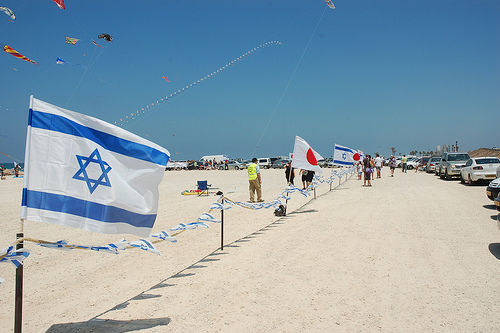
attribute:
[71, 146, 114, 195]
star — blue, white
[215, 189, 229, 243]
post — black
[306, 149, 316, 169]
circle — red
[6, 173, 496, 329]
sand — clean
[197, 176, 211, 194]
chair — blue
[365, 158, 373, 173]
shoulder bag — grey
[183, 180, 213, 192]
beach chair — small, blue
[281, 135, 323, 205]
flag — white, red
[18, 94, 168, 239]
flag — large, blue, white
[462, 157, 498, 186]
car — white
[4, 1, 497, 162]
sky — clear, blue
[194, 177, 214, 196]
chair — on the sand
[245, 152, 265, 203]
man — standing by a flag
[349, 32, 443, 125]
sky — above the kites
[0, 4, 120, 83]
kites — above the beach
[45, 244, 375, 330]
sand — at the beach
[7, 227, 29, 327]
pole —  Israeli flag 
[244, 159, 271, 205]
man —  yellow shirt 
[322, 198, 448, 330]
beach —  sandy 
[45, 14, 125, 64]
kite — sky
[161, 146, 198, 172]
car — parked white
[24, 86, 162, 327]
pole — flag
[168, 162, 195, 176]
suv — silver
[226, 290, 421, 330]
sand —  flag shadow 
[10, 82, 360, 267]
beach — international flags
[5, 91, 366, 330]
beach — various country flags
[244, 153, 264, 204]
man —  neon vest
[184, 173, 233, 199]
chair — blue beach 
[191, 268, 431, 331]
beach —  israeli flags , japanese  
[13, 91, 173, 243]
flag — blue, white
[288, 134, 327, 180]
flag — white, red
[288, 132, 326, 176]
flag — red, white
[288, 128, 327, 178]
flag — white, red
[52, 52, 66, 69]
kite — blue, white, flying